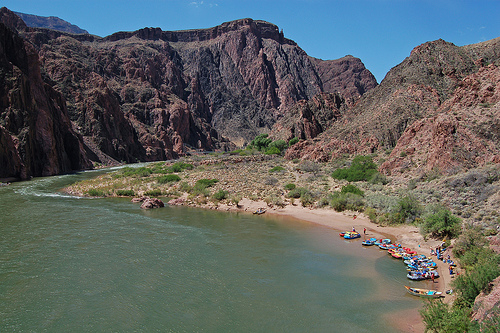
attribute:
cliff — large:
[8, 20, 379, 178]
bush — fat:
[422, 205, 470, 235]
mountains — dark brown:
[86, 31, 476, 133]